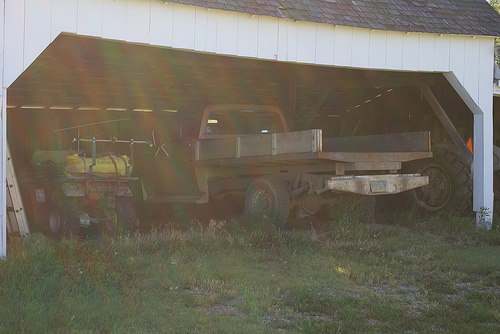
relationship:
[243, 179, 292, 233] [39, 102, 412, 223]
tire on vehicle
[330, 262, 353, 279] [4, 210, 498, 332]
patch on ground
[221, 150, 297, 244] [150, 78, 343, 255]
tire on truck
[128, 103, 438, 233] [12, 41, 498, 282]
cart under a carport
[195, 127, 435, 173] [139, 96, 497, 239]
flatbed of truck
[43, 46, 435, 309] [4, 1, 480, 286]
cart parked under carport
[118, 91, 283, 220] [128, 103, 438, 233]
cab of cart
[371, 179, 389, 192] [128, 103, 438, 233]
license plate on cart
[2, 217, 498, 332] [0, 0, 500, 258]
grass in front of barn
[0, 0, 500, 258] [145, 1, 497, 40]
barn with roof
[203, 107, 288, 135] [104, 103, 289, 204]
window of cab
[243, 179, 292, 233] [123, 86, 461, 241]
tire on truck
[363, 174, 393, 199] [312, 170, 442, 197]
license plate on bumper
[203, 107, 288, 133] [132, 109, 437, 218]
window of truck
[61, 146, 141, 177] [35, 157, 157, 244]
container on cargo rack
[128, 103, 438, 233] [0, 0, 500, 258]
cart in barn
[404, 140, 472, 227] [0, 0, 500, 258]
tire in barn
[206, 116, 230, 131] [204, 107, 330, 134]
sticker in window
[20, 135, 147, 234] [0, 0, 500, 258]
tractor in barn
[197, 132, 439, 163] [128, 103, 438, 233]
bed on cart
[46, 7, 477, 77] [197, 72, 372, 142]
planks on ceiling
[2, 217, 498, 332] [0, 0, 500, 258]
grass by barn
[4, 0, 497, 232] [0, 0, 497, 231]
wooden frame on barn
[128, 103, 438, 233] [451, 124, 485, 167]
cart by triangle